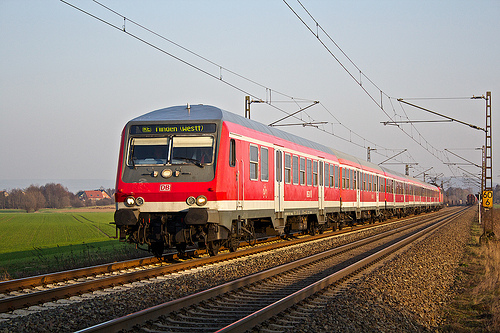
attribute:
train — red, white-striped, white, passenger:
[106, 97, 462, 254]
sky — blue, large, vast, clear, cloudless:
[2, 2, 499, 149]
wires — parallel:
[55, 1, 484, 161]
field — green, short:
[2, 206, 141, 275]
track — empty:
[57, 199, 473, 330]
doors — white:
[271, 148, 291, 216]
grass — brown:
[450, 196, 497, 331]